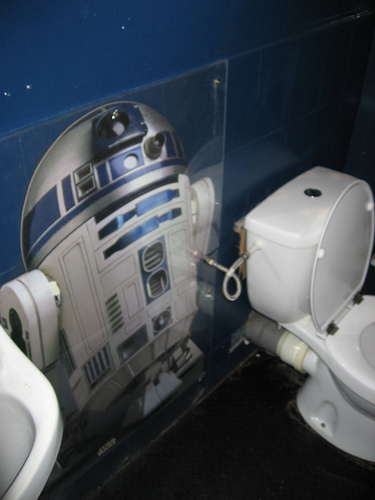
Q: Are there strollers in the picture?
A: No, there are no strollers.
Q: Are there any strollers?
A: No, there are no strollers.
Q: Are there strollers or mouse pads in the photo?
A: No, there are no strollers or mouse pads.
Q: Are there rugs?
A: No, there are no rugs.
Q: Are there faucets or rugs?
A: No, there are no rugs or faucets.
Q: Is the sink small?
A: Yes, the sink is small.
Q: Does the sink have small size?
A: Yes, the sink is small.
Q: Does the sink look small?
A: Yes, the sink is small.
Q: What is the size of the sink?
A: The sink is small.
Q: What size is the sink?
A: The sink is small.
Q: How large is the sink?
A: The sink is small.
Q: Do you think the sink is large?
A: No, the sink is small.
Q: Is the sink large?
A: No, the sink is small.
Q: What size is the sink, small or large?
A: The sink is small.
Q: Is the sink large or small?
A: The sink is small.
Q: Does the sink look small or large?
A: The sink is small.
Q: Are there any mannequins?
A: No, there are no mannequins.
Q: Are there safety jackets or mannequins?
A: No, there are no mannequins or safety jackets.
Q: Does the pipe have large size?
A: Yes, the pipe is large.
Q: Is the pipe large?
A: Yes, the pipe is large.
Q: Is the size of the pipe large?
A: Yes, the pipe is large.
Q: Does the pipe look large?
A: Yes, the pipe is large.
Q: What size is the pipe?
A: The pipe is large.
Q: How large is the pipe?
A: The pipe is large.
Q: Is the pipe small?
A: No, the pipe is large.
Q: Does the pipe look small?
A: No, the pipe is large.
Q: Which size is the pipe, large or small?
A: The pipe is large.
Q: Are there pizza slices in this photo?
A: No, there are no pizza slices.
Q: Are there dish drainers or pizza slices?
A: No, there are no pizza slices or dish drainers.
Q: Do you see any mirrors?
A: No, there are no mirrors.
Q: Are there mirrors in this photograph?
A: No, there are no mirrors.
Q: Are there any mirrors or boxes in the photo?
A: No, there are no mirrors or boxes.